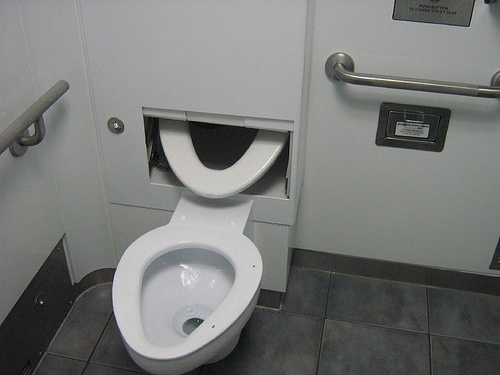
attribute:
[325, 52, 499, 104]
bar — metal, shiny, silver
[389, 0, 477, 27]
sign — square, silver, black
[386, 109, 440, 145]
door — square, silver, metal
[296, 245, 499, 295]
molding — gray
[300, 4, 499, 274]
wall — white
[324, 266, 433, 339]
tile — square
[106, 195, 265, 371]
toilet — white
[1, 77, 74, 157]
bar — wood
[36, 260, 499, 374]
floor — gray, tiled